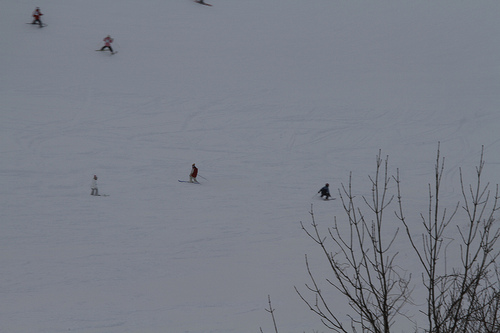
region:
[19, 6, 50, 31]
person skiing down snowy hill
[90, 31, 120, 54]
person skiing down snowy hill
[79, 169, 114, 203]
person skiing down snowy hill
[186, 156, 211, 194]
person skiing down snowy hill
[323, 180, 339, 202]
person skiing down snowy hill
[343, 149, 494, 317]
brown tree without leaves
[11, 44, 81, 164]
white snow on hill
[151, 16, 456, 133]
white snow on hill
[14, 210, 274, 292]
white snow on hill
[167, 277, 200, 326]
the snow is white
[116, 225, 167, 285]
the snow is white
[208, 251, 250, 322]
the snow is white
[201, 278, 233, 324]
the snow is white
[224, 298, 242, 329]
the snow is white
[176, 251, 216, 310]
the snow is white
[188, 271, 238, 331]
the snow is white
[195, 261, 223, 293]
the snow is white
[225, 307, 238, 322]
the snow is white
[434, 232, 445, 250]
branch of a tree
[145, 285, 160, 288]
section of a snowy surface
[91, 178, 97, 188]
a skater on snow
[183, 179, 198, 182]
part of a board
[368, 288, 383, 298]
twig of a tree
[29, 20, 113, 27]
two skaters on snow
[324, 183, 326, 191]
back of a man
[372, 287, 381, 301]
part of a branch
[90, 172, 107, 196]
a skier skiing down the mountain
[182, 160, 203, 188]
a skier skiing down the mountain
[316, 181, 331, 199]
a skier skiing down the mountain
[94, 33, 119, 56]
a skier skiing down the mountain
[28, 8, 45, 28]
a skier skiing down the mountain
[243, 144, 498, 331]
a bare tree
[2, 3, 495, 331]
a snow coverd slope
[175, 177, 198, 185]
a long ski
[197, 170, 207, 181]
a long ski pole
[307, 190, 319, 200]
a long ski pole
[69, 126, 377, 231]
people skiing on a slope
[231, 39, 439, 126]
white snow on the mountain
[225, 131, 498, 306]
a tree in the foreground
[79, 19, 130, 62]
a man in the process of falling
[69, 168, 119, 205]
a person dressed in white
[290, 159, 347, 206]
a man carving in the snow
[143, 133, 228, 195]
a man with ski poles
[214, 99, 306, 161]
lines carved into the snow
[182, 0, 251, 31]
some skis at the top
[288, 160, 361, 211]
a man wearing black